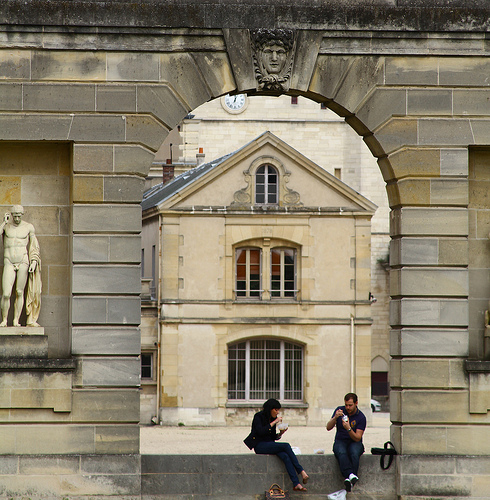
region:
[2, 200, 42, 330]
nude statue outside of building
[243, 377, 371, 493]
2 people sitting on the edge of a step eating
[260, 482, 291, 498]
small brown woman's purse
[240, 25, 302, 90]
stone carving of as face above archway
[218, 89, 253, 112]
clock on the front of a building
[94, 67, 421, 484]
2 people sitting under stone archway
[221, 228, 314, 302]
windows of old building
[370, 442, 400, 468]
man's black bag on the ground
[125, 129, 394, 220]
triangular roof of building behind the archway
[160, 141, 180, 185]
red brick chimney of building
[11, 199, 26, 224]
the head of a statue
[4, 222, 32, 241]
the chest of a statue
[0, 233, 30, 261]
the torso of a statue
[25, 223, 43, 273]
the left arm of a statue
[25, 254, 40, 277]
the left hand of a statue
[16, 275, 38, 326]
the left leg of a statue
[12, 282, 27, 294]
the left knee of a statue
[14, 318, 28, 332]
the left foot of a statue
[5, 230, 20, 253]
the abs of a statue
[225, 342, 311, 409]
the door of a building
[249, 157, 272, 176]
window of a building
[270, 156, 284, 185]
window of a building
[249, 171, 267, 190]
window of a building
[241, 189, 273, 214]
window of a building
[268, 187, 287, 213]
window of a building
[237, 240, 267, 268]
window of a building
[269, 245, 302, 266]
window of a building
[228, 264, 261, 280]
window of a building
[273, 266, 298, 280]
window of a building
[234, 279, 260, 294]
window of a building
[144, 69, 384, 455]
a large round arch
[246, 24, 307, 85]
a face on the top of an arch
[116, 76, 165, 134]
some bricks on a wall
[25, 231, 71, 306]
the arm of a statue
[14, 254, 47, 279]
the hand of a statue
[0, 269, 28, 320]
the legs of a statue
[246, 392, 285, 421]
the head of a woman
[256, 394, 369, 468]
two people eating some ice cream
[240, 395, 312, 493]
Woman sitting cross legged on a wall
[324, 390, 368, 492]
Man sitting cross legged on a wall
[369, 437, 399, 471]
black vinyl bag on wall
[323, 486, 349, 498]
white plastic bag on ground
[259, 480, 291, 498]
brown and tan handbag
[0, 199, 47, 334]
nude statue in wall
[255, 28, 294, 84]
carved face in archway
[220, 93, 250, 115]
clock built into building face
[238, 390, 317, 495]
Woman eating out of container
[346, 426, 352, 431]
Watch on man's wrist